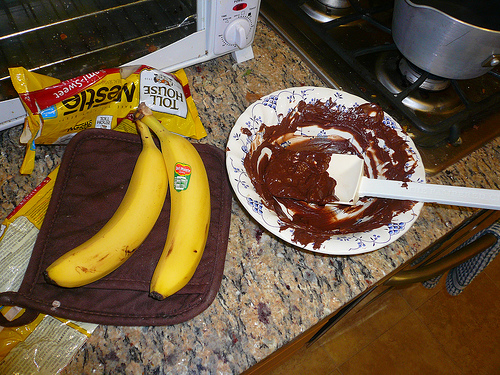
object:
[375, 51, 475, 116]
burner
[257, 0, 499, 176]
stove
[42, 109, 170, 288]
banana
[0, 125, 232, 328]
mitt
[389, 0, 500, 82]
metal pan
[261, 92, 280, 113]
pattern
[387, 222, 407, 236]
pattern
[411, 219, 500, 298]
towel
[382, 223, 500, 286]
bar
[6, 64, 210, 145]
bag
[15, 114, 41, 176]
top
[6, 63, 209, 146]
chcolate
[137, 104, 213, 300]
banana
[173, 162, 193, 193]
banana label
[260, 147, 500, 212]
spatula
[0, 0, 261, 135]
microwave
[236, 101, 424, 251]
chocolate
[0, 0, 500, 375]
countertop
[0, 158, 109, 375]
bag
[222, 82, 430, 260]
paper plate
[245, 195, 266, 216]
pattern